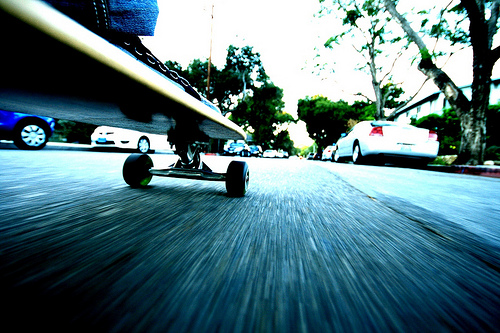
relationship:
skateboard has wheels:
[0, 1, 247, 141] [120, 151, 253, 199]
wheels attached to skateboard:
[120, 151, 253, 199] [0, 1, 247, 141]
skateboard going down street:
[0, 1, 247, 141] [1, 151, 499, 332]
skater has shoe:
[46, 0, 161, 39] [93, 29, 223, 116]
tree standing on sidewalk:
[382, 0, 499, 166] [428, 160, 499, 179]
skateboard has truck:
[0, 1, 247, 141] [151, 131, 226, 184]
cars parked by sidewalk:
[225, 140, 291, 159] [200, 151, 226, 158]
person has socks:
[44, 1, 223, 115] [100, 34, 200, 103]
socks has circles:
[100, 34, 200, 103] [123, 38, 193, 88]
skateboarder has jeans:
[44, 1, 223, 115] [39, 0, 160, 39]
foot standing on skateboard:
[45, 1, 224, 115] [0, 1, 247, 141]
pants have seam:
[39, 0, 160, 39] [91, 0, 113, 32]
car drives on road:
[88, 125, 173, 155] [1, 151, 499, 332]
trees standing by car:
[298, 1, 499, 165] [332, 119, 443, 166]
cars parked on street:
[225, 140, 291, 159] [1, 151, 499, 332]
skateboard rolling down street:
[0, 1, 247, 141] [1, 151, 499, 332]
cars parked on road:
[225, 140, 291, 159] [1, 151, 499, 332]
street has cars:
[1, 151, 499, 332] [225, 140, 291, 159]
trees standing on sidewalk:
[298, 1, 499, 165] [428, 160, 499, 179]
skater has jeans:
[44, 1, 223, 115] [39, 0, 160, 39]